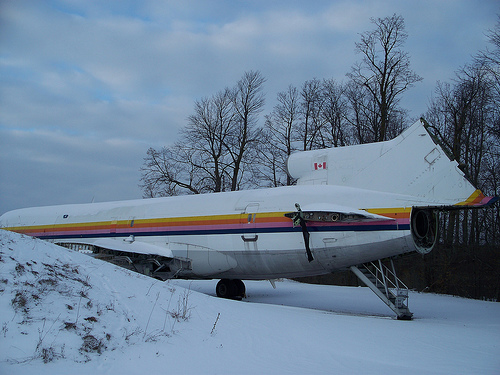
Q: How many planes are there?
A: One.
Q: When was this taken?
A: Evening.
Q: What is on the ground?
A: Snow.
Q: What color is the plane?
A: White with rainbow.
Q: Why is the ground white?
A: Because of the snow.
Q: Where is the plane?
A: Parked on the ground.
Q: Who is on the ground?
A: No one.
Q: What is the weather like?
A: Partly cloudy.